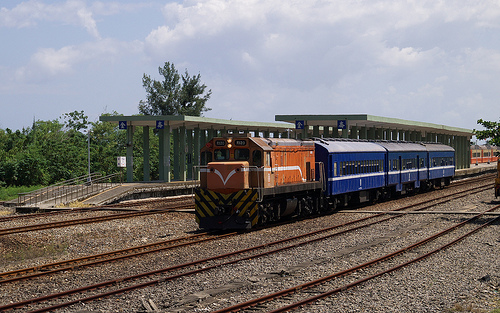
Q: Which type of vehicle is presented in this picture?
A: The vehicle is a locomotive.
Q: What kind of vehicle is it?
A: The vehicle is a locomotive.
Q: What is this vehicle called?
A: This is a locomotive.